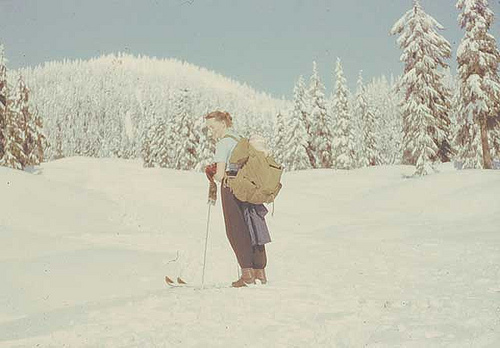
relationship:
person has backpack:
[206, 111, 283, 286] [221, 133, 283, 217]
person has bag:
[204, 110, 266, 287] [220, 134, 286, 216]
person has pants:
[204, 110, 266, 287] [221, 173, 267, 287]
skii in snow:
[164, 275, 287, 287] [189, 257, 302, 298]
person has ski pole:
[204, 110, 266, 287] [201, 171, 215, 289]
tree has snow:
[392, 5, 461, 168] [392, 5, 448, 156]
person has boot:
[204, 110, 266, 287] [231, 268, 255, 286]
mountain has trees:
[3, 53, 404, 173] [12, 52, 282, 163]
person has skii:
[204, 110, 266, 287] [164, 275, 287, 287]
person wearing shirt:
[204, 110, 266, 287] [214, 128, 242, 176]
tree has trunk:
[456, 2, 499, 174] [479, 112, 492, 170]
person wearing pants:
[204, 110, 266, 287] [221, 173, 267, 287]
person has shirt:
[204, 110, 266, 287] [214, 128, 242, 176]